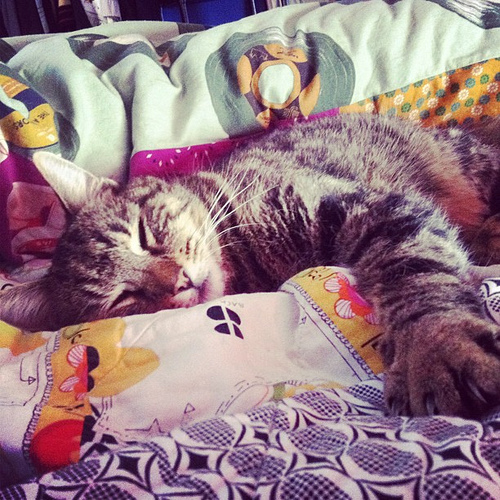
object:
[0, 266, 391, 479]
blanket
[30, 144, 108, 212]
ear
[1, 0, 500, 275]
pillow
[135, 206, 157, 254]
eye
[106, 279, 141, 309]
eye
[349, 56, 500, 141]
stripe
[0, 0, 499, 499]
blanket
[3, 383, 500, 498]
pillow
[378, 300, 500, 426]
paw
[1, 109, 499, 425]
cat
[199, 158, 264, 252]
whiskers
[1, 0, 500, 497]
bed